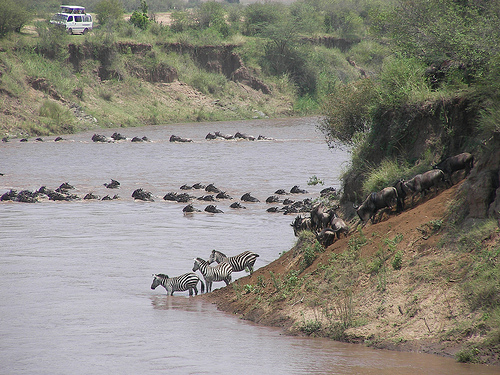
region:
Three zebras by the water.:
[144, 245, 294, 305]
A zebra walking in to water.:
[141, 272, 223, 307]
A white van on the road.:
[48, 3, 99, 35]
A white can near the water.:
[42, 8, 97, 37]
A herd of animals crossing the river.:
[51, 163, 316, 223]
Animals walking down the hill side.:
[350, 142, 487, 223]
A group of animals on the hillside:
[148, 245, 273, 313]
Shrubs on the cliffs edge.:
[345, 10, 485, 151]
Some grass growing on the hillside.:
[342, 235, 460, 347]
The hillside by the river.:
[153, 23, 349, 113]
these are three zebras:
[150, 238, 263, 301]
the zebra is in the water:
[145, 266, 198, 305]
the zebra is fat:
[174, 277, 196, 289]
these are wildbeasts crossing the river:
[26, 165, 248, 226]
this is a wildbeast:
[351, 185, 402, 219]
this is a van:
[48, 5, 98, 32]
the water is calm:
[26, 234, 131, 338]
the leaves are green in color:
[323, 85, 365, 123]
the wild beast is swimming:
[87, 177, 114, 213]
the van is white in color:
[66, 13, 93, 33]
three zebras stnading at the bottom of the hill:
[150, 243, 277, 305]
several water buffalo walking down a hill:
[281, 154, 471, 267]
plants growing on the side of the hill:
[291, 240, 457, 340]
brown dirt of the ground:
[378, 212, 438, 238]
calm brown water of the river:
[99, 323, 250, 363]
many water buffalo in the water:
[14, 163, 290, 230]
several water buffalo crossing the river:
[1, 119, 296, 162]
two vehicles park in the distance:
[35, 0, 107, 40]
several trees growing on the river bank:
[196, 0, 491, 82]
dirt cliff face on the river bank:
[84, 34, 341, 89]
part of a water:
[122, 215, 157, 242]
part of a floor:
[376, 274, 404, 319]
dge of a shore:
[333, 311, 368, 351]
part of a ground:
[383, 283, 405, 321]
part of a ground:
[418, 207, 437, 248]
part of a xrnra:
[184, 255, 204, 282]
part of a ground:
[391, 234, 426, 299]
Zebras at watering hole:
[146, 249, 268, 303]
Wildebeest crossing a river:
[3, 176, 309, 212]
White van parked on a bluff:
[46, 1, 113, 42]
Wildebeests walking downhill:
[341, 120, 493, 250]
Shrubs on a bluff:
[348, 34, 497, 146]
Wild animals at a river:
[106, 172, 270, 310]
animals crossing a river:
[11, 172, 299, 227]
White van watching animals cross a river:
[43, 5, 282, 152]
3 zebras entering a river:
[126, 248, 281, 315]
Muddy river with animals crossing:
[2, 119, 216, 369]